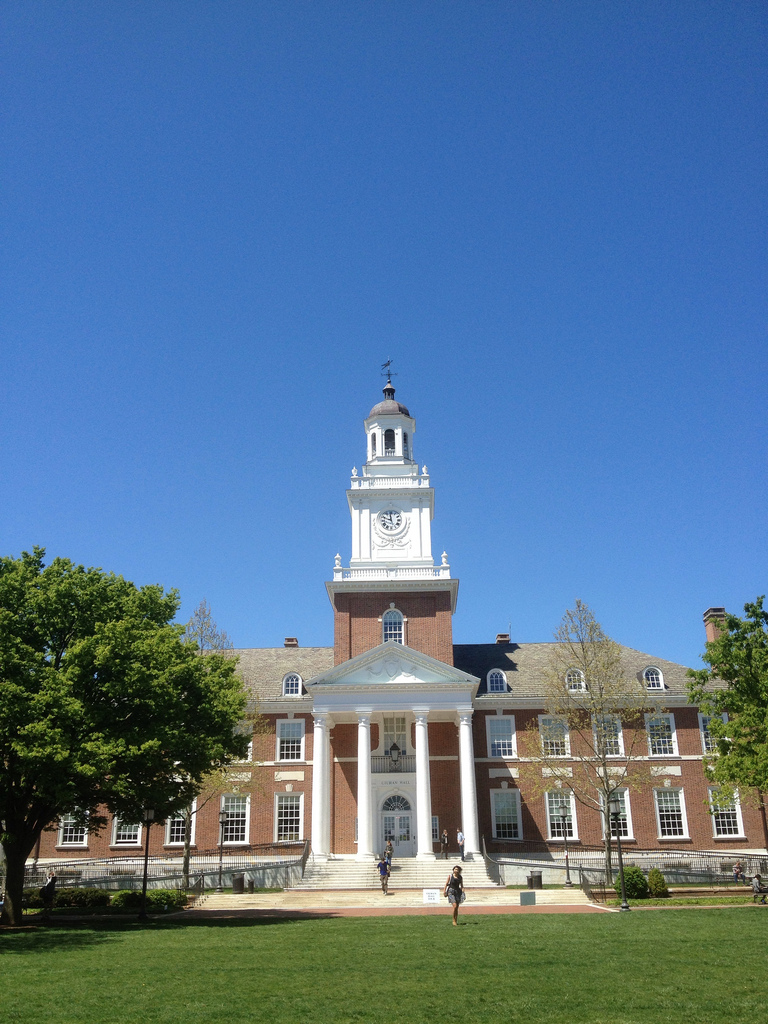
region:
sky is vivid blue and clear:
[0, 1, 765, 671]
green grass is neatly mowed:
[5, 906, 766, 1019]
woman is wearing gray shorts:
[443, 864, 464, 929]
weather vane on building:
[0, 356, 764, 889]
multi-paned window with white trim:
[541, 782, 584, 845]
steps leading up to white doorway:
[282, 769, 504, 889]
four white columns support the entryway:
[301, 637, 487, 864]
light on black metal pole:
[553, 797, 577, 886]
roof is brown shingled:
[185, 643, 741, 704]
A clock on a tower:
[377, 506, 404, 534]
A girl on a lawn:
[443, 863, 472, 927]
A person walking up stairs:
[374, 856, 392, 891]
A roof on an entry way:
[301, 640, 482, 690]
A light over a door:
[381, 739, 404, 768]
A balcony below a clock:
[326, 554, 460, 583]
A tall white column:
[412, 717, 435, 856]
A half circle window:
[385, 790, 413, 816]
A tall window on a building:
[482, 782, 523, 841]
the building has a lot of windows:
[10, 357, 765, 889]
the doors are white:
[379, 812, 410, 854]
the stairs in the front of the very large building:
[2, 355, 765, 886]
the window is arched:
[486, 666, 509, 695]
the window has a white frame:
[650, 784, 692, 843]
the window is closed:
[651, 785, 694, 844]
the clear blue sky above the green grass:
[0, 0, 766, 1019]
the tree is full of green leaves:
[1, 544, 258, 928]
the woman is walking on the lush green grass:
[3, 863, 765, 1022]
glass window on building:
[703, 780, 737, 842]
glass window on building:
[654, 791, 683, 839]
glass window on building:
[598, 787, 629, 837]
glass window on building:
[538, 785, 574, 834]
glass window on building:
[491, 791, 522, 839]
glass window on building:
[273, 795, 298, 839]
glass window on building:
[224, 795, 244, 838]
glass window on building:
[165, 808, 189, 842]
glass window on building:
[115, 818, 139, 842]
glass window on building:
[63, 807, 87, 839]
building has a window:
[276, 718, 302, 760]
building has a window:
[275, 794, 302, 844]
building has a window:
[225, 790, 248, 842]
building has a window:
[166, 794, 195, 844]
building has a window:
[116, 810, 137, 842]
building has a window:
[62, 803, 82, 840]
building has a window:
[229, 722, 248, 754]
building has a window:
[490, 712, 518, 758]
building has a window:
[536, 712, 572, 754]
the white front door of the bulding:
[372, 772, 420, 855]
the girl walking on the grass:
[443, 864, 467, 926]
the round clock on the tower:
[377, 505, 406, 533]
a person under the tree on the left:
[36, 875, 61, 917]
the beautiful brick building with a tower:
[24, 358, 766, 890]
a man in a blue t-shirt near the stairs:
[375, 853, 392, 894]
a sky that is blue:
[32, 152, 692, 360]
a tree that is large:
[17, 583, 232, 945]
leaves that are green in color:
[48, 631, 241, 795]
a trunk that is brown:
[0, 798, 57, 927]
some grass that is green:
[100, 929, 426, 1021]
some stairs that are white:
[342, 828, 491, 902]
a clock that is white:
[366, 493, 418, 550]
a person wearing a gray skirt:
[440, 862, 468, 926]